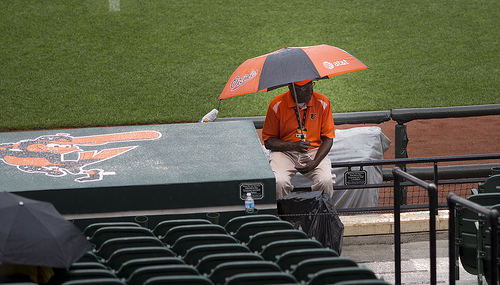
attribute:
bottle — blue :
[241, 192, 255, 214]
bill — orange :
[294, 77, 310, 86]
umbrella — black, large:
[213, 36, 380, 113]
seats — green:
[61, 212, 388, 283]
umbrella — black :
[4, 190, 101, 271]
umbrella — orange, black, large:
[208, 32, 368, 109]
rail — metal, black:
[388, 166, 444, 283]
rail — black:
[441, 186, 498, 283]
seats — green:
[223, 207, 391, 281]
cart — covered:
[288, 188, 337, 252]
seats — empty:
[83, 210, 382, 283]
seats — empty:
[452, 174, 498, 281]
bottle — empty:
[198, 105, 218, 122]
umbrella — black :
[213, 27, 395, 130]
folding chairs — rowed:
[2, 210, 383, 282]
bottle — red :
[199, 105, 221, 122]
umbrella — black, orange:
[226, 42, 358, 89]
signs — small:
[343, 168, 370, 188]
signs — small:
[239, 176, 262, 201]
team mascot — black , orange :
[0, 126, 170, 183]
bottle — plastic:
[244, 192, 255, 212]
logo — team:
[2, 126, 134, 182]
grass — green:
[384, 26, 449, 96]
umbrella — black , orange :
[217, 42, 369, 99]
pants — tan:
[265, 146, 335, 198]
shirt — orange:
[259, 90, 336, 142]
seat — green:
[229, 212, 282, 227]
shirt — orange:
[259, 90, 342, 152]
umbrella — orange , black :
[217, 40, 367, 105]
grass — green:
[4, 2, 493, 109]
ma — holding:
[258, 103, 372, 203]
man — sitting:
[246, 75, 365, 202]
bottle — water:
[243, 188, 258, 214]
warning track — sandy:
[261, 106, 484, 204]